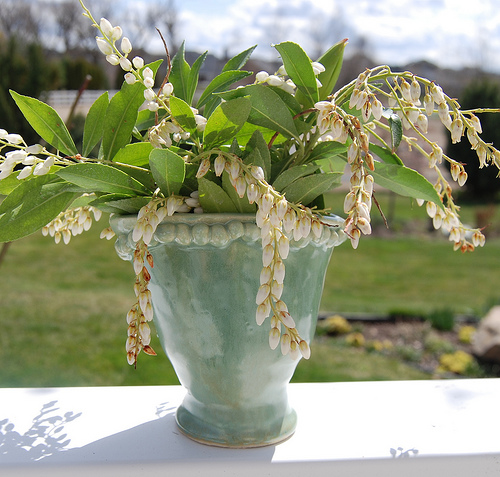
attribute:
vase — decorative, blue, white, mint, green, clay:
[107, 209, 350, 451]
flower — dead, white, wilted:
[30, 151, 61, 181]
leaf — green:
[53, 159, 158, 201]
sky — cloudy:
[39, 0, 497, 72]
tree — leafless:
[41, 1, 87, 95]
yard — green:
[1, 198, 498, 388]